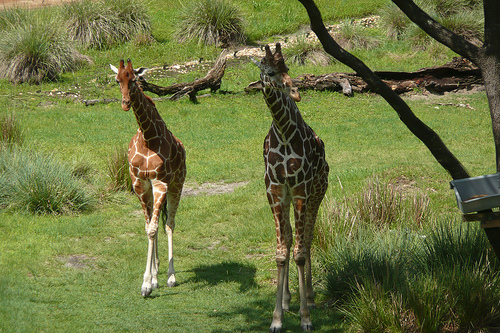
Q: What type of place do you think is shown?
A: It is a field.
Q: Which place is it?
A: It is a field.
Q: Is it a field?
A: Yes, it is a field.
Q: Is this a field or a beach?
A: It is a field.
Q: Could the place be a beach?
A: No, it is a field.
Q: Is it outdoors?
A: Yes, it is outdoors.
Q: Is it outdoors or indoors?
A: It is outdoors.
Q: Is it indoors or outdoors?
A: It is outdoors.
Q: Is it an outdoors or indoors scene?
A: It is outdoors.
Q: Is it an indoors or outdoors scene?
A: It is outdoors.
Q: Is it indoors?
A: No, it is outdoors.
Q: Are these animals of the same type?
A: Yes, all the animals are giraffes.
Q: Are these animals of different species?
A: No, all the animals are giraffes.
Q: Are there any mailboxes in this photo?
A: No, there are no mailboxes.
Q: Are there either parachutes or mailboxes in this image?
A: No, there are no mailboxes or parachutes.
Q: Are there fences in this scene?
A: No, there are no fences.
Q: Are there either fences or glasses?
A: No, there are no fences or glasses.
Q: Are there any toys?
A: No, there are no toys.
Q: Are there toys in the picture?
A: No, there are no toys.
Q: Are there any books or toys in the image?
A: No, there are no toys or books.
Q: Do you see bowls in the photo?
A: No, there are no bowls.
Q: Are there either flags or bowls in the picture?
A: No, there are no bowls or flags.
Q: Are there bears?
A: No, there are no bears.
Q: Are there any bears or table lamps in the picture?
A: No, there are no bears or table lamps.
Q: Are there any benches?
A: No, there are no benches.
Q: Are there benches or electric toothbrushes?
A: No, there are no benches or electric toothbrushes.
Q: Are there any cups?
A: No, there are no cups.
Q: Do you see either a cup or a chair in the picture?
A: No, there are no cups or chairs.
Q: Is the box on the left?
A: No, the box is on the right of the image.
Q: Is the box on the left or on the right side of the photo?
A: The box is on the right of the image.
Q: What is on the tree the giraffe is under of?
A: The box is on the tree.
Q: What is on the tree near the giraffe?
A: The box is on the tree.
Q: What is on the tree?
A: The box is on the tree.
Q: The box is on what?
A: The box is on the tree.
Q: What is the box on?
A: The box is on the tree.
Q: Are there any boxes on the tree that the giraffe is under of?
A: Yes, there is a box on the tree.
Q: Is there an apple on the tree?
A: No, there is a box on the tree.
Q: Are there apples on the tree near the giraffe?
A: No, there is a box on the tree.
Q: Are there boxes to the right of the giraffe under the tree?
A: Yes, there is a box to the right of the giraffe.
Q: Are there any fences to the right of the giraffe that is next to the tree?
A: No, there is a box to the right of the giraffe.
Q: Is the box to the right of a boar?
A: No, the box is to the right of a giraffe.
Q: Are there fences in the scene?
A: No, there are no fences.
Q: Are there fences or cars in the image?
A: No, there are no fences or cars.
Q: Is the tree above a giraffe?
A: Yes, the tree is above a giraffe.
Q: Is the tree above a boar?
A: No, the tree is above a giraffe.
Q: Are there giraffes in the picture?
A: Yes, there is a giraffe.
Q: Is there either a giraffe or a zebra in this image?
A: Yes, there is a giraffe.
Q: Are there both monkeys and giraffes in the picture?
A: No, there is a giraffe but no monkeys.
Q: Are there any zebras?
A: No, there are no zebras.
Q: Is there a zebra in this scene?
A: No, there are no zebras.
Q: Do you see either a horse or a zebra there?
A: No, there are no zebras or horses.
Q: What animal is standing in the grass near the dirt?
A: The giraffe is standing in the grass.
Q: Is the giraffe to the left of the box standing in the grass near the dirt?
A: Yes, the giraffe is standing in the grass.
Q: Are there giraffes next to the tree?
A: Yes, there is a giraffe next to the tree.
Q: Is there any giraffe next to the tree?
A: Yes, there is a giraffe next to the tree.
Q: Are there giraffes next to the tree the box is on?
A: Yes, there is a giraffe next to the tree.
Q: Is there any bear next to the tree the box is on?
A: No, there is a giraffe next to the tree.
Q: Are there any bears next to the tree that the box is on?
A: No, there is a giraffe next to the tree.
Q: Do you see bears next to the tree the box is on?
A: No, there is a giraffe next to the tree.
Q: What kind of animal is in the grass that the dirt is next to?
A: The animal is a giraffe.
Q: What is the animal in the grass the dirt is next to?
A: The animal is a giraffe.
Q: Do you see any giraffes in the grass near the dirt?
A: Yes, there is a giraffe in the grass.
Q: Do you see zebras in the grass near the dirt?
A: No, there is a giraffe in the grass.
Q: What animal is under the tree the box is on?
A: The giraffe is under the tree.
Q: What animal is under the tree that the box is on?
A: The giraffe is under the tree.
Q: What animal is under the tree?
A: The giraffe is under the tree.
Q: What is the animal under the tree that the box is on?
A: The animal is a giraffe.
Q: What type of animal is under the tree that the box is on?
A: The animal is a giraffe.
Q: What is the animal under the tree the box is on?
A: The animal is a giraffe.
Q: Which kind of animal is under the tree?
A: The animal is a giraffe.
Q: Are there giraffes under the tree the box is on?
A: Yes, there is a giraffe under the tree.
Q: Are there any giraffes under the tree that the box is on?
A: Yes, there is a giraffe under the tree.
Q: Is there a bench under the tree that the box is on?
A: No, there is a giraffe under the tree.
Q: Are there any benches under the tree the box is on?
A: No, there is a giraffe under the tree.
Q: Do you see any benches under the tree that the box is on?
A: No, there is a giraffe under the tree.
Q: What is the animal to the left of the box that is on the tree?
A: The animal is a giraffe.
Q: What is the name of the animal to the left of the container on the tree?
A: The animal is a giraffe.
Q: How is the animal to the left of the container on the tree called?
A: The animal is a giraffe.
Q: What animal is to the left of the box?
A: The animal is a giraffe.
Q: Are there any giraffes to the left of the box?
A: Yes, there is a giraffe to the left of the box.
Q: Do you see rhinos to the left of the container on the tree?
A: No, there is a giraffe to the left of the box.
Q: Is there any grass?
A: Yes, there is grass.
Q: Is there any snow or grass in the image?
A: Yes, there is grass.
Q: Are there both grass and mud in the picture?
A: No, there is grass but no mud.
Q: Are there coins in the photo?
A: No, there are no coins.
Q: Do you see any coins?
A: No, there are no coins.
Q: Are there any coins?
A: No, there are no coins.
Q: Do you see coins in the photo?
A: No, there are no coins.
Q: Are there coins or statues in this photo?
A: No, there are no coins or statues.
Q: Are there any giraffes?
A: Yes, there is a giraffe.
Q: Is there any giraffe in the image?
A: Yes, there is a giraffe.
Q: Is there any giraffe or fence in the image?
A: Yes, there is a giraffe.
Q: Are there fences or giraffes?
A: Yes, there is a giraffe.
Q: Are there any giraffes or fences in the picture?
A: Yes, there is a giraffe.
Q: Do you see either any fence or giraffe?
A: Yes, there is a giraffe.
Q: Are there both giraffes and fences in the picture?
A: No, there is a giraffe but no fences.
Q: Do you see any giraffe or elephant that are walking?
A: Yes, the giraffe is walking.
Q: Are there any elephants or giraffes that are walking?
A: Yes, the giraffe is walking.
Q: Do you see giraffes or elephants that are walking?
A: Yes, the giraffe is walking.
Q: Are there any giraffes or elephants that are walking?
A: Yes, the giraffe is walking.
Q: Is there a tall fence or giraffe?
A: Yes, there is a tall giraffe.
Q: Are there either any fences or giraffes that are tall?
A: Yes, the giraffe is tall.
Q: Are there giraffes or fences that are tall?
A: Yes, the giraffe is tall.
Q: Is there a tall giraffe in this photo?
A: Yes, there is a tall giraffe.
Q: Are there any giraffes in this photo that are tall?
A: Yes, there is a giraffe that is tall.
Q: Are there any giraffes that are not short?
A: Yes, there is a tall giraffe.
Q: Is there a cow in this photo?
A: No, there are no cows.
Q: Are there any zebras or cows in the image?
A: No, there are no cows or zebras.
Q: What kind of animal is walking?
A: The animal is a giraffe.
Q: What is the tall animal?
A: The animal is a giraffe.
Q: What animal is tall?
A: The animal is a giraffe.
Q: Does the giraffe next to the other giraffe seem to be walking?
A: Yes, the giraffe is walking.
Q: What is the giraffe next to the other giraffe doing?
A: The giraffe is walking.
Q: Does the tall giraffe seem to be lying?
A: No, the giraffe is walking.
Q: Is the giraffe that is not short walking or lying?
A: The giraffe is walking.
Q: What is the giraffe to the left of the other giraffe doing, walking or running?
A: The giraffe is walking.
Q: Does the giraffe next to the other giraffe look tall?
A: Yes, the giraffe is tall.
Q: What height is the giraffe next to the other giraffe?
A: The giraffe is tall.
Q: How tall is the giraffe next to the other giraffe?
A: The giraffe is tall.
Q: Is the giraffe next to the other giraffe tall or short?
A: The giraffe is tall.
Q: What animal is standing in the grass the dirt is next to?
A: The giraffe is standing in the grass.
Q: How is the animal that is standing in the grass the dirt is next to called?
A: The animal is a giraffe.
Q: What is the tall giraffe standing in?
A: The giraffe is standing in the grass.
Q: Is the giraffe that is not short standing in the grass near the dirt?
A: Yes, the giraffe is standing in the grass.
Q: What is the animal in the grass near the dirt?
A: The animal is a giraffe.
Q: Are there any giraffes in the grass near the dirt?
A: Yes, there is a giraffe in the grass.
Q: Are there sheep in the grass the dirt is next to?
A: No, there is a giraffe in the grass.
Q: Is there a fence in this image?
A: No, there are no fences.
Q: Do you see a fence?
A: No, there are no fences.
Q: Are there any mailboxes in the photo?
A: No, there are no mailboxes.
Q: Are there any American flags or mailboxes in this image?
A: No, there are no mailboxes or American flags.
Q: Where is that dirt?
A: The dirt is in the field.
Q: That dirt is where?
A: The dirt is in the field.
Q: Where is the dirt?
A: The dirt is in the field.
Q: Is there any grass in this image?
A: Yes, there is grass.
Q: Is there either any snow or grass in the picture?
A: Yes, there is grass.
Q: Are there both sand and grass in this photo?
A: No, there is grass but no sand.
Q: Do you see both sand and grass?
A: No, there is grass but no sand.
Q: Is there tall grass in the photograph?
A: Yes, there is tall grass.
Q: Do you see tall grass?
A: Yes, there is tall grass.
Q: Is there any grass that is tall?
A: Yes, there is grass that is tall.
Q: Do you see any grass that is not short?
A: Yes, there is tall grass.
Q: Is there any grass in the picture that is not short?
A: Yes, there is tall grass.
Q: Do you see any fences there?
A: No, there are no fences.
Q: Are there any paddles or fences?
A: No, there are no fences or paddles.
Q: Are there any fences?
A: No, there are no fences.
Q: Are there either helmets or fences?
A: No, there are no fences or helmets.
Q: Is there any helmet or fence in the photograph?
A: No, there are no fences or helmets.